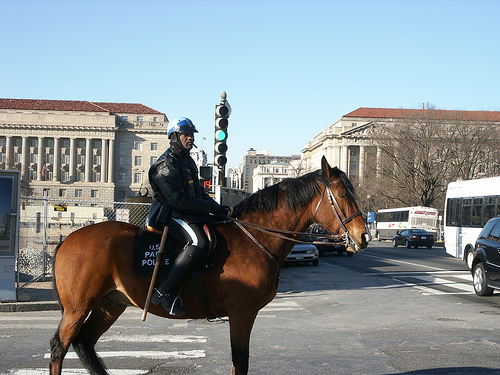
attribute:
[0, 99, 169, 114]
roof — red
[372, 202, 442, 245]
bus — white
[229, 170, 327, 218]
mane — black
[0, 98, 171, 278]
building — light beige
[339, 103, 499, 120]
roof — red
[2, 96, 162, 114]
roof — red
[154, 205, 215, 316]
pants — black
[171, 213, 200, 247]
stripe — white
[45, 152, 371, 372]
horse — brown, brown and black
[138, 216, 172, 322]
baton — brown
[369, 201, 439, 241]
bus — white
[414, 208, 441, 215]
stripe — red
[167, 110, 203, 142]
helmet — worn, blue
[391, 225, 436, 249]
car — black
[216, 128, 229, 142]
signal — t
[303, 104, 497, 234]
building — large, light beige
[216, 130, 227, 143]
light — green, red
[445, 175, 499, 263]
bus — white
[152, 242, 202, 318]
boots — black